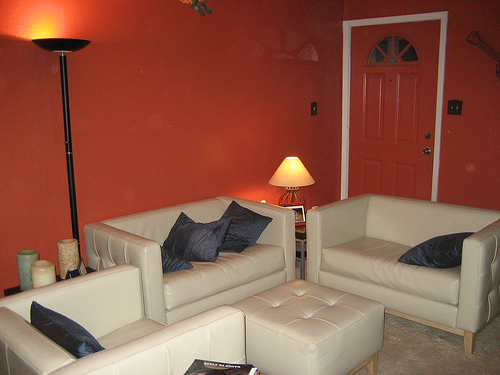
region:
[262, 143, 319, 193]
yellow lamp shade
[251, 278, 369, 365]
white colored ottoman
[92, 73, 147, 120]
orange colored wall in living room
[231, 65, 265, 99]
orange colored wall in living room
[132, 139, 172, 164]
orange colored wall in living room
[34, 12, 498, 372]
this is a living room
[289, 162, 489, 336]
this is a love seat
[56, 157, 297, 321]
this is a sofa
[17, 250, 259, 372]
this is a chair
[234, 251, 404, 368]
this is an ottoman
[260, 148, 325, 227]
this is a table lamp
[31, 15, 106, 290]
this is a floor lamp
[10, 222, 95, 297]
a set of candles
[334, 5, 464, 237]
this is a door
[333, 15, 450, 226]
the door is red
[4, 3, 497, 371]
room with white furniture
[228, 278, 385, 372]
room has white ottoman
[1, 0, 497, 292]
wall has red wall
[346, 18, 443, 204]
door is painted red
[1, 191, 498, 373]
couches have blue throw pillows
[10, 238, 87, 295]
candles on top of side table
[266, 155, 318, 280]
lamp on top of side table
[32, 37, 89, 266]
lamp next to wall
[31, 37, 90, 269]
black lamp next to wall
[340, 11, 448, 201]
door has window insert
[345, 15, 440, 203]
A door is red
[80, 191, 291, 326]
A white leather couch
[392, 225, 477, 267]
A blue colored pillow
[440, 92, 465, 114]
Light switch is on the wall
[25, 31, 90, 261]
A tall black lamp is turned on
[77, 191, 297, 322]
Three blue pillows on a white couch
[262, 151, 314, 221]
A lamp with a white lampshade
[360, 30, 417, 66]
A window on a red door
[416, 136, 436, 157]
Doorknob on a door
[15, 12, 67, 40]
Light glare on the red wall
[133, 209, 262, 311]
a couch with pillows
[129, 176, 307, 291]
a couch with three pillows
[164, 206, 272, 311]
a couch with three blue pillows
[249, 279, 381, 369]
a white ottoman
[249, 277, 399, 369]
a square white ottoman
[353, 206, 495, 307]
a pillow on the couch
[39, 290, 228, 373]
a couch with a blue pillow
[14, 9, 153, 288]
a tall lamp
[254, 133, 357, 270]
a short lamp on table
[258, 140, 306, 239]
a lamp on the table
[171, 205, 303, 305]
pillows on the couch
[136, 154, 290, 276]
blue pillows on teh couch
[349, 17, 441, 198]
The door is red.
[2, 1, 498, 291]
a room with bright orange walls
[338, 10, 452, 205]
orange entry door with white trim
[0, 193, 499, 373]
a white leather living room set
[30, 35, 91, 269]
tall black floor lamp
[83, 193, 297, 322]
three blue pillows on a white sofa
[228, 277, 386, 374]
white leather ottoman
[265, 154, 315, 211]
small table lamp with a white shade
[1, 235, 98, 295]
three pillar candles on a table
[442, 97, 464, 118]
black wall plate of a light switch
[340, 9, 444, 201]
arched windows on an entry door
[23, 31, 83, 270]
A tall black floor lamp.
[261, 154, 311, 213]
A small lamp turned on the table.